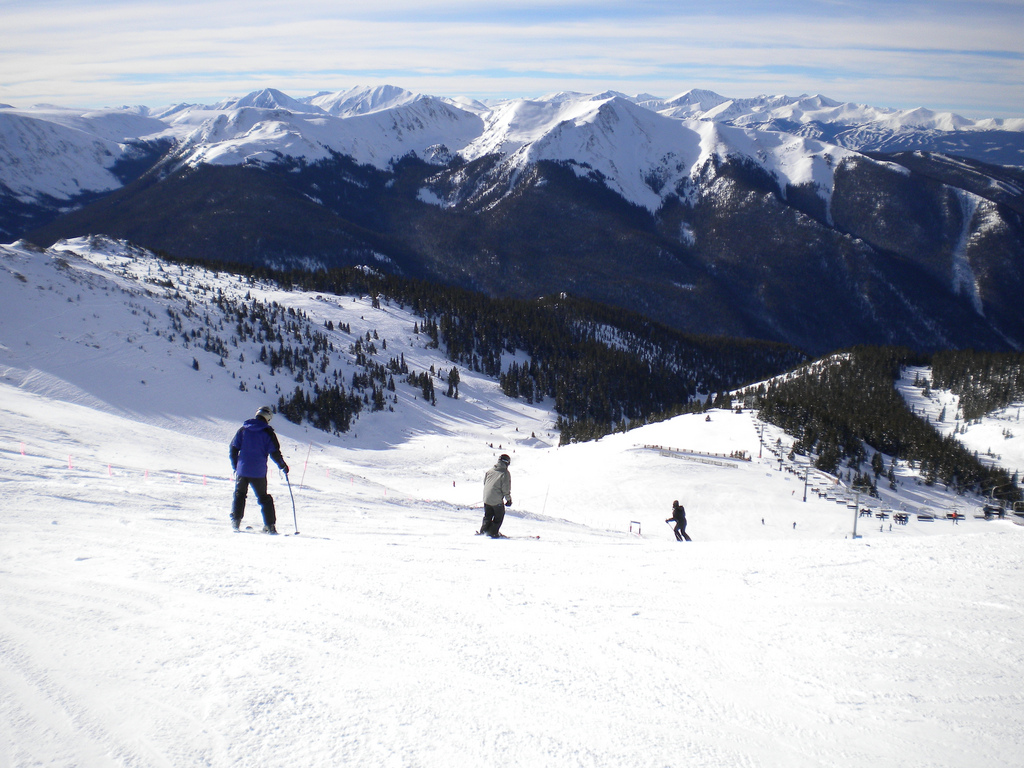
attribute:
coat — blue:
[207, 386, 320, 518]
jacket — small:
[471, 459, 511, 514]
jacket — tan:
[482, 465, 513, 504]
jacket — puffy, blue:
[220, 413, 287, 496]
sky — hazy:
[427, 16, 946, 157]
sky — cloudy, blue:
[293, 13, 901, 128]